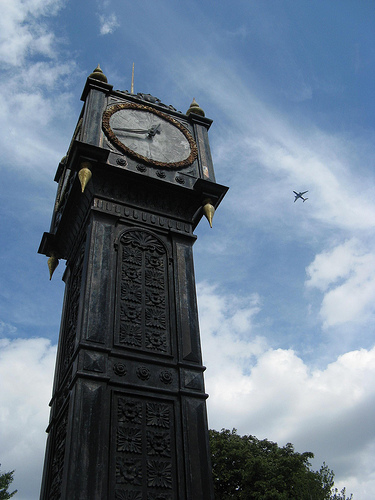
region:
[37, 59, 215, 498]
A tall, ornate, black clock tower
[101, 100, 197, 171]
A large clock face on a clock tower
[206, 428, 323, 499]
A large bushy tree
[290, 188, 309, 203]
A distant airplane flying in the sky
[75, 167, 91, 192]
A spike pointing downward atop a clock tower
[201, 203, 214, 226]
A golden ornamental spike pointing downward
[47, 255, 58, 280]
A golden ornamental spike pointing downward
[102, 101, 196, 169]
A clock face displaying the time of 12:40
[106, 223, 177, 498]
Ornate designs on the side of a tower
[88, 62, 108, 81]
A golden ornamental spike pointing upwards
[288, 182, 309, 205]
Plane flying high in the air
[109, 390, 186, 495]
Etched pattern on stone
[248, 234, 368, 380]
Sky with fluffy white clouds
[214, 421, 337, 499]
Bushy section of leaves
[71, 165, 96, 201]
Decorative spikes on clock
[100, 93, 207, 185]
Clock with two hands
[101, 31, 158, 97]
Antennae at top of clock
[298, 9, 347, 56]
Blue sky with no clouds.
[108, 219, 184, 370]
Small section of design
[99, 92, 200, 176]
Clock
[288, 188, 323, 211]
a jet plane in the sky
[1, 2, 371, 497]
a cloudy blue sky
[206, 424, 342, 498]
a tree behind a clock tower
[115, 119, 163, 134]
black hands on the face of a clock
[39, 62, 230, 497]
a tall black clock tower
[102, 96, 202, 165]
a round clock face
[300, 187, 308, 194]
the wing of an airplane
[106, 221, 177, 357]
an arched pattern on a clock tower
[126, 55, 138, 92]
a gold pole on top of a clock tower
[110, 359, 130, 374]
a rosette on the side of a clock tower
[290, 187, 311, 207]
the plane is high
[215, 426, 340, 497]
the tree is healthy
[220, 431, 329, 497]
the tree is full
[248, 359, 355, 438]
the cloud is white and fluffy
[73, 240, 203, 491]
the piller is gray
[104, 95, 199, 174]
the clock reads 1:40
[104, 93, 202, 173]
the clock is round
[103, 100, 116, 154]
the clock is rusted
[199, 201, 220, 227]
the decoration is gold and pointy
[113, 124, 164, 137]
the hands of the clock are black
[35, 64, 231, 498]
a tall iron clock tower.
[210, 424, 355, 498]
a tree on the side of a clock.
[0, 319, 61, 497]
a large gray cloud.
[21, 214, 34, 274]
a section of hazy blue sky.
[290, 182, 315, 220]
a passenger jet flying over a clock tower.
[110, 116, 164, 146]
black hands on a clock.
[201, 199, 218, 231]
a pointy object on a clock tower.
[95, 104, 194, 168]
a clock on a clock tower.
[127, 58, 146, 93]
a lighting rod on a clock.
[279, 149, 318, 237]
a plane flying through a cloudy sky.